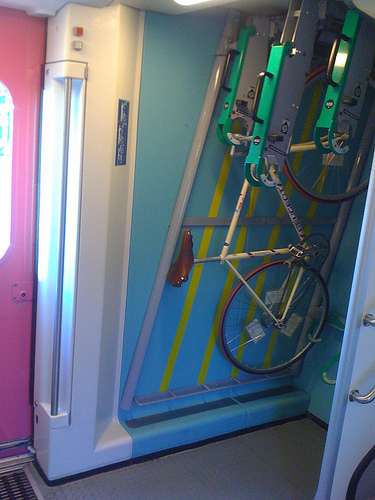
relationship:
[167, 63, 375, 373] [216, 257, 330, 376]
bicycle has wheel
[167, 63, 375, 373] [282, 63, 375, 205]
bicycle has tire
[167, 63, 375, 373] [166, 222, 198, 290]
bicycle has seat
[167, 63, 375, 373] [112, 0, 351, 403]
bicycle hanging from a rack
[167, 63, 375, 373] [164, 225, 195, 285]
bicycle has seat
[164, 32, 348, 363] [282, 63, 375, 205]
bicycle has tire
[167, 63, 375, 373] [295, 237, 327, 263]
bicycle has pedal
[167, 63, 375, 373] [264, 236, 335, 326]
bicycle has chain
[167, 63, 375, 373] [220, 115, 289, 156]
bicycle has bars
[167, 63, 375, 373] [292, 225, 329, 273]
bicycle has chainring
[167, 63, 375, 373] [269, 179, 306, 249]
bicycle has brand name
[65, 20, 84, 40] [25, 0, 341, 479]
red light on wall